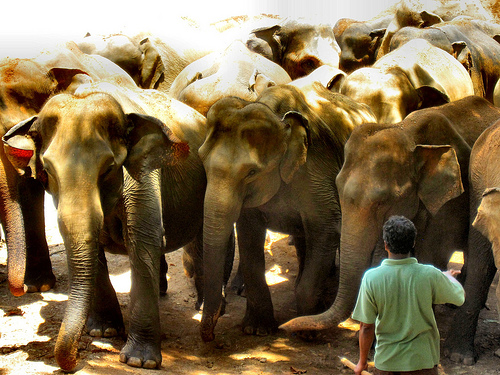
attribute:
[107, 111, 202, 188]
ears — long, outstretched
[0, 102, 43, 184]
ears — long, outstretched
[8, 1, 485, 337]
group — large